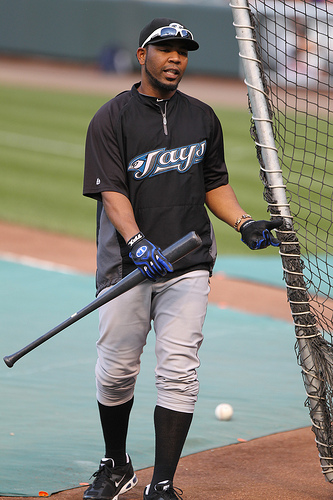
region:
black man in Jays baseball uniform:
[59, 4, 285, 314]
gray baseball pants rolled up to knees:
[69, 243, 217, 497]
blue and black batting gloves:
[3, 177, 285, 401]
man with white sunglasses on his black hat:
[121, 8, 208, 100]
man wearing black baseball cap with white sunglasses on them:
[131, 8, 200, 105]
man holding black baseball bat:
[2, 11, 286, 409]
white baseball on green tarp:
[207, 391, 244, 434]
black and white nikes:
[70, 445, 191, 498]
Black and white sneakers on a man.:
[82, 451, 196, 499]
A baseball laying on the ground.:
[213, 400, 233, 420]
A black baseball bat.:
[0, 230, 204, 367]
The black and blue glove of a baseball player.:
[124, 234, 176, 283]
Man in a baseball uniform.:
[81, 16, 248, 493]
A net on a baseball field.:
[227, 1, 331, 497]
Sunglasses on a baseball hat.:
[135, 17, 201, 53]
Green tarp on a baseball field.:
[1, 257, 330, 496]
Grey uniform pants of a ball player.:
[98, 271, 209, 413]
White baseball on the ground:
[211, 401, 233, 421]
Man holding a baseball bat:
[1, 16, 283, 499]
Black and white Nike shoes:
[78, 453, 182, 499]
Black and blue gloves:
[123, 217, 282, 280]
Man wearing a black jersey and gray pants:
[3, 18, 287, 499]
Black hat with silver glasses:
[137, 14, 199, 55]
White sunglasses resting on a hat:
[137, 23, 192, 53]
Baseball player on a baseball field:
[1, 19, 282, 498]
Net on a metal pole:
[226, 0, 332, 488]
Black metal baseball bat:
[3, 230, 200, 380]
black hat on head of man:
[140, 18, 198, 49]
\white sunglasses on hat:
[156, 24, 196, 38]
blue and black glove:
[129, 227, 180, 279]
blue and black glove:
[236, 215, 281, 247]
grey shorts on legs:
[91, 272, 210, 415]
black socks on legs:
[108, 407, 189, 473]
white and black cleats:
[84, 456, 136, 498]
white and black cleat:
[145, 484, 182, 498]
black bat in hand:
[0, 235, 201, 369]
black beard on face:
[141, 66, 162, 88]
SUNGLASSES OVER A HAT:
[145, 24, 196, 44]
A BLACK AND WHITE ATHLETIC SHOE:
[78, 455, 142, 498]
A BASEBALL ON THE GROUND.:
[214, 395, 234, 427]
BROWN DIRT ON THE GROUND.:
[208, 450, 300, 498]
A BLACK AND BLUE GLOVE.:
[128, 238, 177, 284]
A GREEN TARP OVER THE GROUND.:
[14, 426, 66, 460]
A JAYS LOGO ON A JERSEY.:
[124, 143, 216, 178]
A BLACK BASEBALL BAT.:
[10, 225, 222, 378]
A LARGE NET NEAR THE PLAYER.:
[244, 141, 332, 384]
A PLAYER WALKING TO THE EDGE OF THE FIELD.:
[67, 10, 279, 499]